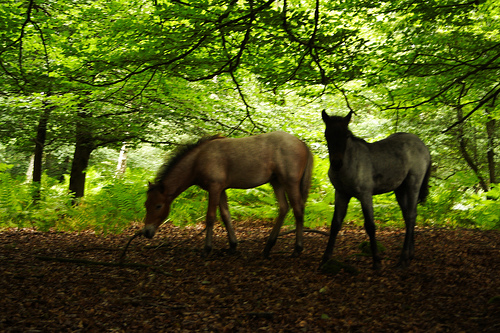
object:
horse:
[321, 108, 431, 267]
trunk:
[68, 113, 94, 207]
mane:
[146, 130, 224, 194]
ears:
[321, 109, 330, 123]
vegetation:
[0, 178, 62, 233]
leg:
[275, 170, 309, 257]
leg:
[261, 182, 290, 254]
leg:
[219, 190, 242, 249]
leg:
[205, 183, 224, 253]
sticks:
[30, 231, 178, 279]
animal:
[321, 109, 431, 270]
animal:
[143, 131, 313, 258]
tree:
[1, 0, 306, 209]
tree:
[0, 50, 73, 209]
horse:
[141, 131, 315, 256]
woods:
[3, 0, 499, 333]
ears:
[343, 109, 353, 124]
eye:
[155, 204, 162, 210]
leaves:
[0, 224, 499, 333]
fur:
[146, 133, 225, 194]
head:
[142, 179, 170, 239]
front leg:
[319, 188, 352, 262]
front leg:
[357, 190, 381, 271]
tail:
[417, 160, 432, 206]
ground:
[0, 224, 500, 333]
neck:
[164, 144, 197, 198]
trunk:
[485, 93, 496, 182]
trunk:
[33, 106, 50, 200]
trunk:
[456, 108, 488, 192]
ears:
[161, 182, 169, 196]